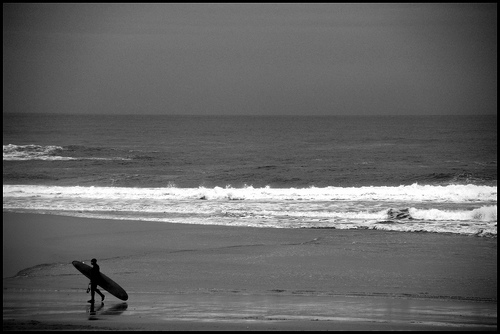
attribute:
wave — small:
[3, 175, 498, 245]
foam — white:
[157, 175, 499, 202]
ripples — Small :
[3, 177, 498, 234]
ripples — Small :
[3, 137, 132, 164]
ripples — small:
[70, 152, 454, 182]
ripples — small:
[218, 172, 354, 234]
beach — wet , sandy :
[0, 185, 495, 332]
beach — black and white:
[0, 208, 499, 331]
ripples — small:
[0, 114, 499, 234]